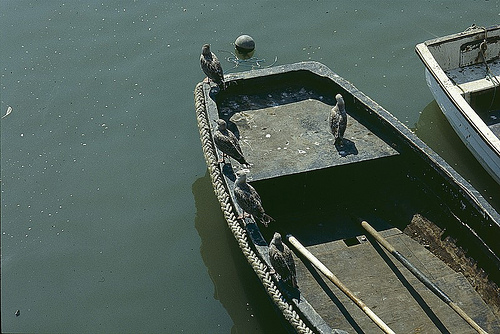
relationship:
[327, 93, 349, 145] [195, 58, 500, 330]
bird on boat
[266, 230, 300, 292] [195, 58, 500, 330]
bird on boat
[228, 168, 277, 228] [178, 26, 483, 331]
bird on boat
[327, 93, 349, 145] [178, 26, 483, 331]
bird on boat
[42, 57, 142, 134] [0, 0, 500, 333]
ripples in water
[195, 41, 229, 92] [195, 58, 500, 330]
bird on boat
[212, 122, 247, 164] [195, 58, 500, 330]
bird on boat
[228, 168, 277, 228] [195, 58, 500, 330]
bird on boat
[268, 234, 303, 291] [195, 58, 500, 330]
bird on boat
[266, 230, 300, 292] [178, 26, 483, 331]
bird on boat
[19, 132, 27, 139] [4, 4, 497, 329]
spot in water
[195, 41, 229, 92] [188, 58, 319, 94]
bird on front edge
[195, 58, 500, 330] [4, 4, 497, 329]
boat in water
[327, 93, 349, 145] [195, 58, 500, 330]
bird sitting on boat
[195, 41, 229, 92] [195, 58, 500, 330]
bird sitting on boat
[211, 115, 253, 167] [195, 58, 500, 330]
bird sitting on boat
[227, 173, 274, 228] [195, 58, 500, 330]
bird sitting on boat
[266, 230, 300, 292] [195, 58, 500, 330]
bird sitting on boat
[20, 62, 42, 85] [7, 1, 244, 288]
spot in water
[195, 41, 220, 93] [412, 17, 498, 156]
bird on boat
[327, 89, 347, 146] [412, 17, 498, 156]
bird on boat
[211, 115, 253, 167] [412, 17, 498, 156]
bird on boat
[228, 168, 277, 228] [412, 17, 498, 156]
bird on boat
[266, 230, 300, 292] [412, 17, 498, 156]
bird on boat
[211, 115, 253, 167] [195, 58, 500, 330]
bird on boat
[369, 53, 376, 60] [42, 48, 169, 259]
speck in water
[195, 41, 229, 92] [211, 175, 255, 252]
bird on edge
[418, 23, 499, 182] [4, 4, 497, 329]
boat in water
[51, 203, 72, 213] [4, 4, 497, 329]
spot in water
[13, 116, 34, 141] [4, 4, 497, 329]
spot in water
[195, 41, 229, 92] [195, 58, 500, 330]
bird are on boat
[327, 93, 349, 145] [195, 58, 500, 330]
bird are on boat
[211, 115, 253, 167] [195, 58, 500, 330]
bird are on boat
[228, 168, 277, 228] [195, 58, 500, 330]
bird are on boat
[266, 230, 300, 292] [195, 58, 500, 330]
bird are on boat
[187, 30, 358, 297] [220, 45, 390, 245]
oars are in boat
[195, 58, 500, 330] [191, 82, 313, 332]
boat has rope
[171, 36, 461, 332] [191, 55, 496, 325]
boat in water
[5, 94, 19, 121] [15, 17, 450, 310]
speck in water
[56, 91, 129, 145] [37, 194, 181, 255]
spot in water